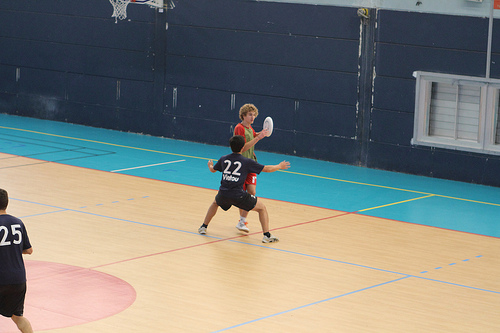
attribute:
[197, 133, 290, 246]
frisbee player — indoors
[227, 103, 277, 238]
frisbee player — indoors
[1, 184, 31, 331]
frisbee player — indoors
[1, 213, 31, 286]
shirt — navy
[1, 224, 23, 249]
numbers — large, 25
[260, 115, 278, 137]
frisbee — white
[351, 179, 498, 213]
line — yellow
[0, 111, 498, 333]
floor — wooden, blue, brown, red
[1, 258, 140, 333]
circle — red, pink, large, painted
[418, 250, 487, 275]
line — blue, dotted, broken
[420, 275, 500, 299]
line — blue, solid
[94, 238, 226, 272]
line — pink, painted, drawn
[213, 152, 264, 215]
jersey — black, medium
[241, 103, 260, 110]
hair — bushy, blonde, curly, light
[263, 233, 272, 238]
sock — black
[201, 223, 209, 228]
sock — black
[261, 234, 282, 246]
sneaker — gym shoe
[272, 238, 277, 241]
trim — blue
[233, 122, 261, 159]
shirt — red, gray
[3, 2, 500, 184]
wall — painted, blue, gray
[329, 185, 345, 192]
paint — neon blue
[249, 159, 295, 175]
arm — outstretched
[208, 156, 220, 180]
arm — outstretched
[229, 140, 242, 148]
hair — dark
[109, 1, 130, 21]
net — basketball net, white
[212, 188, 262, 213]
shorts — black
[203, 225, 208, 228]
sock — black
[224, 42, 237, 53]
paint — peeling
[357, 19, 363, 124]
marks — scuff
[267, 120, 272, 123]
ball — white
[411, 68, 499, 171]
window — white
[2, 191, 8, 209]
hair — brown